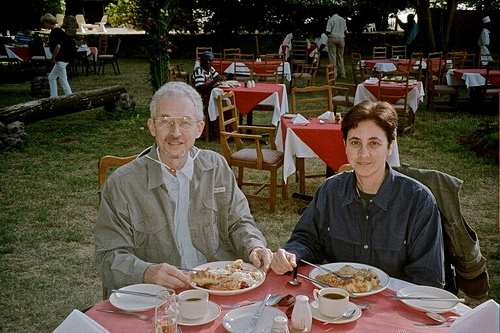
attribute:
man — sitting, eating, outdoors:
[94, 81, 273, 299]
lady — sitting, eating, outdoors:
[269, 101, 445, 288]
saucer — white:
[165, 300, 221, 326]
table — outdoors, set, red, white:
[84, 263, 473, 332]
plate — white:
[188, 259, 266, 295]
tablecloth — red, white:
[52, 263, 499, 331]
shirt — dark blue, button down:
[282, 161, 446, 290]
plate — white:
[309, 262, 390, 297]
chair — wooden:
[216, 90, 288, 211]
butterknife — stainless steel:
[297, 271, 331, 289]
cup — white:
[313, 287, 350, 318]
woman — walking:
[40, 13, 71, 96]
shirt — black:
[48, 26, 70, 61]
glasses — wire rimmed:
[149, 116, 199, 129]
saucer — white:
[309, 299, 362, 325]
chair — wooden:
[291, 85, 334, 195]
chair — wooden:
[98, 155, 137, 303]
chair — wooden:
[378, 71, 412, 136]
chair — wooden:
[290, 51, 321, 89]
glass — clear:
[155, 289, 177, 332]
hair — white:
[148, 82, 205, 123]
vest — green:
[389, 162, 490, 300]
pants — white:
[48, 61, 71, 98]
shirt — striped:
[191, 65, 219, 87]